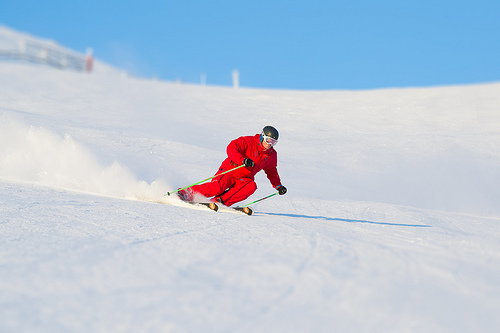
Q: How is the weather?
A: It is clear.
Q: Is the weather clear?
A: Yes, it is clear.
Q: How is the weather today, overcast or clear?
A: It is clear.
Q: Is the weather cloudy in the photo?
A: No, it is clear.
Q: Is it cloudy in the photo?
A: No, it is clear.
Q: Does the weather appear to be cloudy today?
A: No, it is clear.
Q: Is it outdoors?
A: Yes, it is outdoors.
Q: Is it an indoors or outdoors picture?
A: It is outdoors.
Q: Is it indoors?
A: No, it is outdoors.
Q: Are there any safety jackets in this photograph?
A: No, there are no safety jackets.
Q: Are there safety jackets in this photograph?
A: No, there are no safety jackets.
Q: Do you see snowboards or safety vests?
A: No, there are no safety vests or snowboards.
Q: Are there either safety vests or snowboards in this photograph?
A: No, there are no safety vests or snowboards.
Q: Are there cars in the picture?
A: No, there are no cars.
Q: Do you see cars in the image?
A: No, there are no cars.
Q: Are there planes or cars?
A: No, there are no cars or planes.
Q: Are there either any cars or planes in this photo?
A: No, there are no cars or planes.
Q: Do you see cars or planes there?
A: No, there are no cars or planes.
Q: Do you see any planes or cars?
A: No, there are no cars or planes.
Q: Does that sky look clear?
A: Yes, the sky is clear.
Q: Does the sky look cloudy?
A: No, the sky is clear.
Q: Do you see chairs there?
A: No, there are no chairs.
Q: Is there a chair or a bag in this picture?
A: No, there are no chairs or bags.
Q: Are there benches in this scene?
A: No, there are no benches.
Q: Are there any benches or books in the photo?
A: No, there are no benches or books.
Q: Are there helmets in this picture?
A: Yes, there is a helmet.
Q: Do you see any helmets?
A: Yes, there is a helmet.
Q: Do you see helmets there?
A: Yes, there is a helmet.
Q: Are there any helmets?
A: Yes, there is a helmet.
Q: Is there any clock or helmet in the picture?
A: Yes, there is a helmet.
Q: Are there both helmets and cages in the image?
A: No, there is a helmet but no cages.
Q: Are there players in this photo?
A: No, there are no players.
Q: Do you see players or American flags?
A: No, there are no players or American flags.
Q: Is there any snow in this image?
A: Yes, there is snow.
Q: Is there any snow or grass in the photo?
A: Yes, there is snow.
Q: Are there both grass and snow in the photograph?
A: No, there is snow but no grass.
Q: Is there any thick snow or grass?
A: Yes, there is thick snow.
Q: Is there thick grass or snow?
A: Yes, there is thick snow.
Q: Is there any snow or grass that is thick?
A: Yes, the snow is thick.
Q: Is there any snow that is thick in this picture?
A: Yes, there is thick snow.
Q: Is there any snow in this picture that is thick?
A: Yes, there is snow that is thick.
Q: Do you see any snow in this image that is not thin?
A: Yes, there is thick snow.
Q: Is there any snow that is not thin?
A: Yes, there is thick snow.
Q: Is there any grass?
A: No, there is no grass.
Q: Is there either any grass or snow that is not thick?
A: No, there is snow but it is thick.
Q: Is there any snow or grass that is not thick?
A: No, there is snow but it is thick.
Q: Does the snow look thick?
A: Yes, the snow is thick.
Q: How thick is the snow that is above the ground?
A: The snow is thick.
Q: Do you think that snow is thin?
A: No, the snow is thick.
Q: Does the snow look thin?
A: No, the snow is thick.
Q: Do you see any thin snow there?
A: No, there is snow but it is thick.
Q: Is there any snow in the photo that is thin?
A: No, there is snow but it is thick.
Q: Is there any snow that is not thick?
A: No, there is snow but it is thick.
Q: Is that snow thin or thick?
A: The snow is thick.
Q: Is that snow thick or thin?
A: The snow is thick.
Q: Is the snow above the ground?
A: Yes, the snow is above the ground.